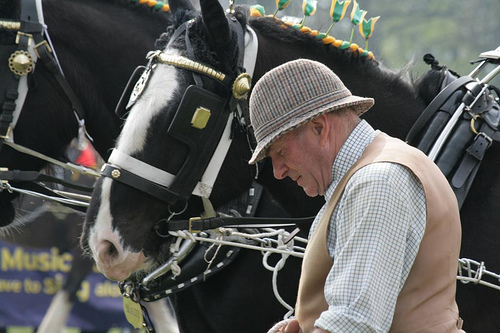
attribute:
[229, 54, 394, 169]
hat — brown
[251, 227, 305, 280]
knot — rope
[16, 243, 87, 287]
letters — yellow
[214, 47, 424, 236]
man — looking down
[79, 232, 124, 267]
nose — white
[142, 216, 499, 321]
rope —  white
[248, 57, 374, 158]
cap — grey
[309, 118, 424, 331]
shirt — checked, white, checkered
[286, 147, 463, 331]
sweater — half , brown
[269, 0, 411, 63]
mane — horse's , green , yellow 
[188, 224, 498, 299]
rope — white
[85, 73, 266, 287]
fur — black 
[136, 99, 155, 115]
spot — white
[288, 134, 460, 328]
vest — brown 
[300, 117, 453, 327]
shirt — blue,  white